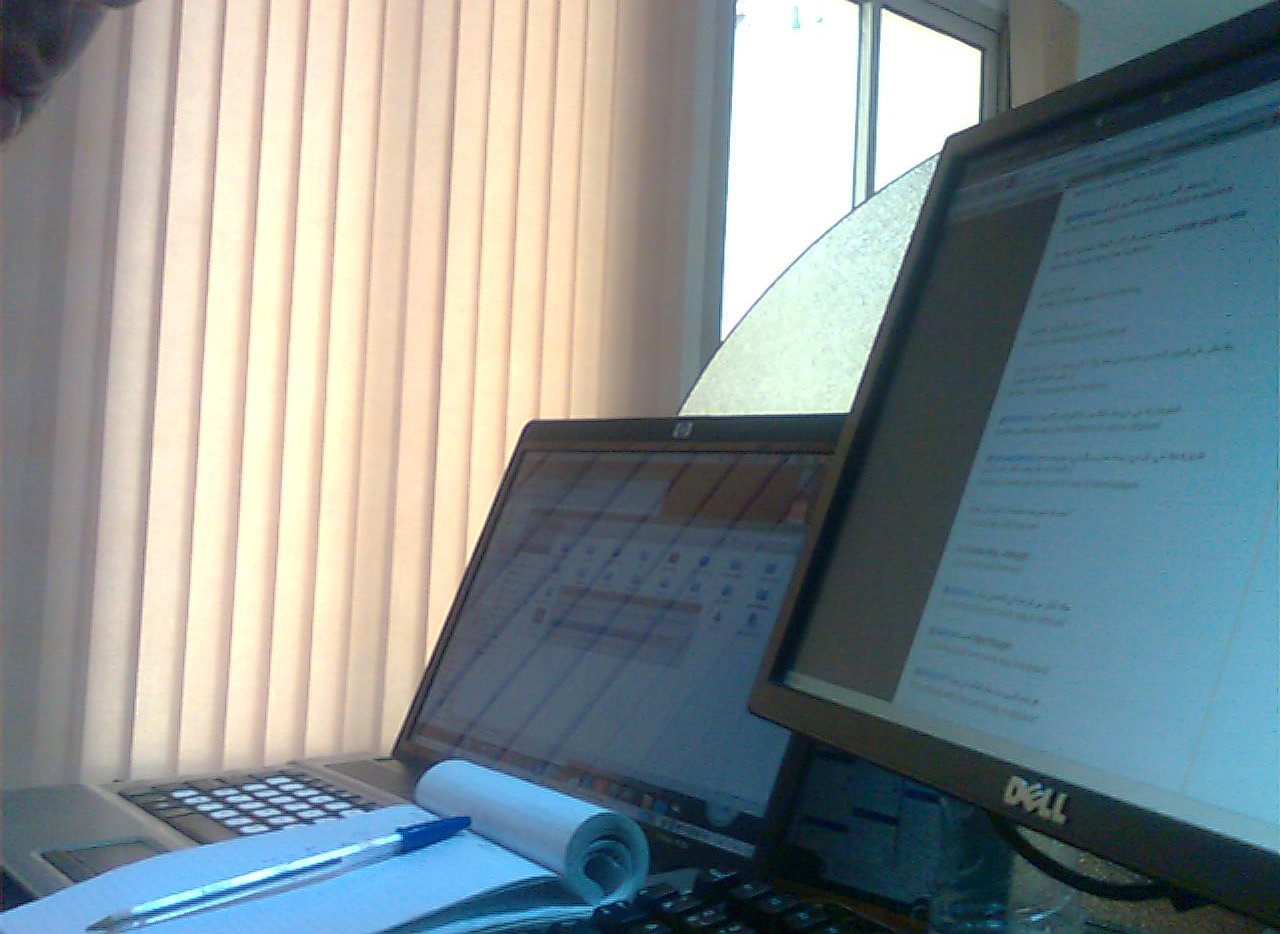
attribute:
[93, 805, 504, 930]
pen — blue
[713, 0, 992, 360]
glass door — Sliding , glass 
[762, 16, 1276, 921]
computer monitor — Dell , flatscreen 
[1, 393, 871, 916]
laptop — open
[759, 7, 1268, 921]
black screen — black 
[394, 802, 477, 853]
cap — blue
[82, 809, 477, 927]
pen — blue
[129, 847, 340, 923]
ink — blue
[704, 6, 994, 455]
windows — large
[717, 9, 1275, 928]
monitor — computer, dell, black, desktop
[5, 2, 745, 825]
shades — window, closed, floor to ceiling